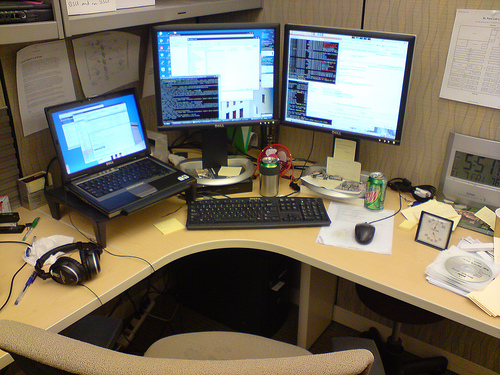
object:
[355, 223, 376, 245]
mouse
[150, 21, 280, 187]
computer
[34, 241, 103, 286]
headphone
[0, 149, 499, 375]
desk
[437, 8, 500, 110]
paper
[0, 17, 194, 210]
wall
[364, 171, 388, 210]
can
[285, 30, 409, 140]
computer screen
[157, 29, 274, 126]
computer screen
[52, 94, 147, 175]
computer screen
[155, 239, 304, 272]
curve edge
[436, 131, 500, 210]
clock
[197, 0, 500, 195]
wall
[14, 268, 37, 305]
pen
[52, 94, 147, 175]
screen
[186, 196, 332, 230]
keyboard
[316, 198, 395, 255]
paper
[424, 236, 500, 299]
paper